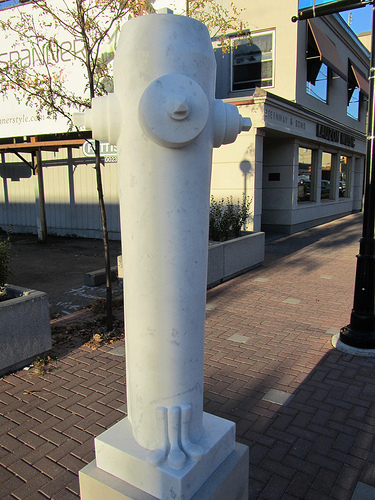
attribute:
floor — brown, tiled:
[2, 215, 373, 496]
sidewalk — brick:
[31, 234, 373, 499]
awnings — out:
[301, 17, 373, 100]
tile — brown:
[232, 309, 313, 384]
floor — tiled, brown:
[221, 287, 358, 463]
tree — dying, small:
[1, 0, 117, 321]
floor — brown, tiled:
[244, 287, 347, 426]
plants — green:
[206, 190, 255, 240]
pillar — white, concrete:
[72, 10, 252, 497]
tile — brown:
[204, 218, 373, 499]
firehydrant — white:
[68, 8, 250, 499]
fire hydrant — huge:
[66, 6, 261, 497]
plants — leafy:
[206, 194, 250, 243]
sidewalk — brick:
[19, 390, 90, 441]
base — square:
[73, 407, 259, 495]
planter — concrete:
[1, 271, 62, 378]